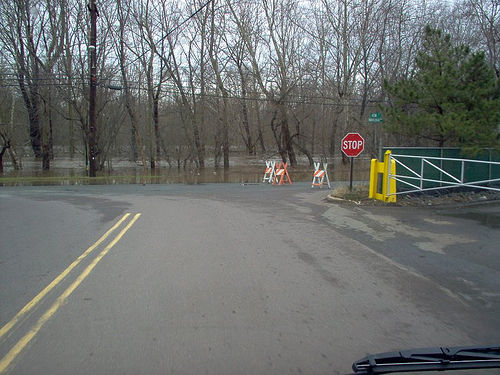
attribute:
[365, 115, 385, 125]
sign — green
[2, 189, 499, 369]
street — white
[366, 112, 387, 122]
sign — green, metal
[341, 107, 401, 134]
sign — green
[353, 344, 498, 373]
wiper — black, windshield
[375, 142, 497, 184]
fence — Green, metal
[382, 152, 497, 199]
gate — silver 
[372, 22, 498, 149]
tree — Large, green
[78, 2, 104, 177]
pole — wooden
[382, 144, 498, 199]
fence — green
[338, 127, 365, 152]
sign — red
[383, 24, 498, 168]
tree — large, green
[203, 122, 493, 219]
fence — metal 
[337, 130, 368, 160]
sign — red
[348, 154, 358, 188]
pole — metal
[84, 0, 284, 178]
trees — bare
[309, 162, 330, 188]
barrier — orange, white, standing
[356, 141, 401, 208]
barrier — Yellow , plastic